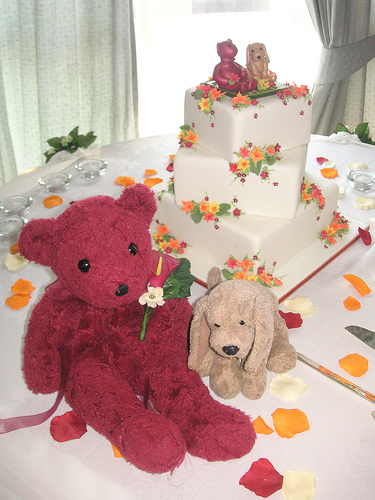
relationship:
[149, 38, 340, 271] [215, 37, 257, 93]
cake has figurines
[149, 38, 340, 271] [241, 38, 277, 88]
cake has figurines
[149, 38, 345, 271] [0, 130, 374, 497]
cake on table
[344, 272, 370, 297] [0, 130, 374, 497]
petal on table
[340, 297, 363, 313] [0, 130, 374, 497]
petal on table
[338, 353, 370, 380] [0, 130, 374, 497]
petal on table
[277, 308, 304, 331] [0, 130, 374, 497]
petal on table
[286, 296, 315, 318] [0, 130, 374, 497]
petal on table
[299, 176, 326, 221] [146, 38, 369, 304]
flower on cake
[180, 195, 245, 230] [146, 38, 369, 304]
flower on cake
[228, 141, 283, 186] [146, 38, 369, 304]
flower on cake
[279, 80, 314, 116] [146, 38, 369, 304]
flowers on cake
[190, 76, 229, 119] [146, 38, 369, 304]
flowers on cake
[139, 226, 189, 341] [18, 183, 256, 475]
flower on animal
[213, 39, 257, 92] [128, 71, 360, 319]
figurines on cake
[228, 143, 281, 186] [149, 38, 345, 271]
flower on cake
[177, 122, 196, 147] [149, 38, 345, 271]
flower on cake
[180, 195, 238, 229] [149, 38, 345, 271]
flower on cake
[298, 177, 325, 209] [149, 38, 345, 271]
flower on cake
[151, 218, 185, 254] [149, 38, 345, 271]
flower on cake